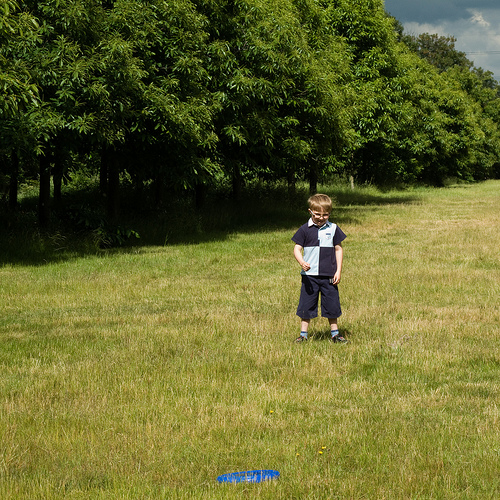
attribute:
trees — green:
[1, 0, 499, 247]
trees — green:
[3, 0, 498, 216]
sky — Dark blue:
[403, 1, 498, 46]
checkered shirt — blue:
[288, 215, 348, 275]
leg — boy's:
[319, 277, 346, 343]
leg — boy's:
[293, 275, 318, 343]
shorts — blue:
[295, 265, 344, 317]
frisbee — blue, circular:
[213, 470, 282, 485]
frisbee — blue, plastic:
[198, 453, 303, 490]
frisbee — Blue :
[206, 457, 272, 499]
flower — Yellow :
[295, 450, 304, 462]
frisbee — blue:
[216, 466, 285, 483]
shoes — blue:
[291, 323, 348, 355]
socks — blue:
[296, 327, 346, 341]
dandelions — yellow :
[262, 404, 327, 464]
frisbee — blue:
[214, 464, 280, 499]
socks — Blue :
[292, 316, 349, 343]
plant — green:
[93, 220, 140, 254]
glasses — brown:
[309, 210, 330, 221]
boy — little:
[257, 145, 411, 359]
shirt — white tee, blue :
[278, 205, 363, 276]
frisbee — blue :
[193, 450, 305, 492]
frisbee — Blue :
[212, 465, 283, 486]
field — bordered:
[6, 30, 496, 317]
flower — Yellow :
[313, 450, 324, 456]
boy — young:
[284, 188, 356, 342]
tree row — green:
[1, 0, 498, 257]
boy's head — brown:
[304, 194, 335, 213]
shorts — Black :
[297, 277, 340, 318]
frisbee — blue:
[223, 464, 291, 483]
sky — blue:
[442, 16, 487, 36]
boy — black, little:
[289, 186, 349, 343]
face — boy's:
[311, 209, 331, 225]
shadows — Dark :
[124, 202, 248, 252]